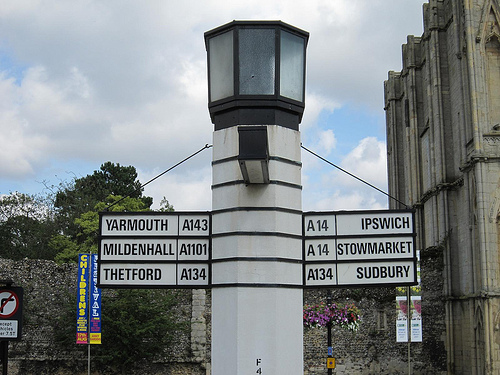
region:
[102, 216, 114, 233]
The letter is black.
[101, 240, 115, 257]
The letter is black.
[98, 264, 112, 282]
The letter is black.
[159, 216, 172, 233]
The letter is black.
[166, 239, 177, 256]
The letter is black.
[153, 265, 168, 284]
The letter is black.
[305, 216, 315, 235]
The letter is black.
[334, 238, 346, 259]
The letter is black.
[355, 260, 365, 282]
The letter is black.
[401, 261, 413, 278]
The letter is black.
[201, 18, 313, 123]
light on top of a white concrete post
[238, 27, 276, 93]
glass panes surrounding light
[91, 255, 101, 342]
blue banner hanging on a pole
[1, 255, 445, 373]
stone wall behind post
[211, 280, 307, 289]
thin black stripes around post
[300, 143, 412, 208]
black cable connected to post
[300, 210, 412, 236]
white sign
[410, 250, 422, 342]
white banner hanging on a pole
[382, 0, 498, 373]
large stone building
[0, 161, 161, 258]
trees behind wall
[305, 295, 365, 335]
pretty white and purple flowers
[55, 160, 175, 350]
trees behind the stone wall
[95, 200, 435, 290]
signs with numbers on it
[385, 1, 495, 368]
tall building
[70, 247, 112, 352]
blue tall signs on pole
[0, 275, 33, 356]
traffic sign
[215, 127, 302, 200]
small light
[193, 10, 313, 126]
big light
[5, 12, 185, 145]
a lot of clouds in the sky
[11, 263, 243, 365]
tall stone wall in the background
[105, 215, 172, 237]
yarmouth is black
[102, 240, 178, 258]
mildenhall is black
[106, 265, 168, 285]
thetford is black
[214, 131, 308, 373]
the column is black and white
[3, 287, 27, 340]
the sign says no right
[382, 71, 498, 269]
the building is made of bricks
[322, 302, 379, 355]
the wall is made of bricks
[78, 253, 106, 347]
the sign is blue and yellow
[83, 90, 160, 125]
clouds are in the sky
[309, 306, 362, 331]
the flowers are purple and white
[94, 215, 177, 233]
the black and white YARMOUTH sign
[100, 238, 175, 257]
the black and white MILDENHALL sign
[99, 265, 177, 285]
the black and white THETFORD sign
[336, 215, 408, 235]
the black and white IPSWICH sign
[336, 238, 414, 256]
the black and white STOWMARKET sign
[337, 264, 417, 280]
the black and white SUDBURY sign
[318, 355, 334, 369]
the bright yellow small sign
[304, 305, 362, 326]
a large purple flowered hanging basket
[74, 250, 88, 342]
a blue yellow what and red vertical sign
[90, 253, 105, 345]
a blue yellow what and red vertical sign